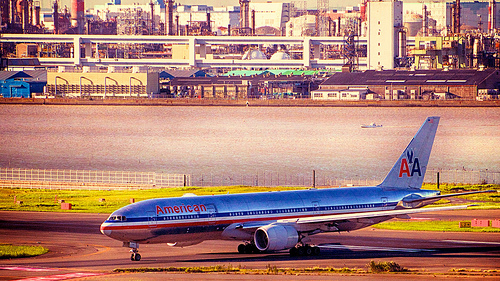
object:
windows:
[162, 216, 167, 221]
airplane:
[98, 115, 500, 261]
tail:
[376, 114, 442, 192]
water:
[0, 108, 499, 180]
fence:
[0, 166, 191, 191]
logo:
[396, 156, 423, 179]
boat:
[358, 118, 384, 130]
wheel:
[129, 248, 143, 262]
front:
[98, 196, 159, 249]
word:
[156, 203, 208, 214]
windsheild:
[105, 214, 126, 225]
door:
[146, 210, 158, 229]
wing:
[274, 204, 468, 225]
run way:
[0, 207, 500, 281]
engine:
[250, 219, 302, 255]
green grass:
[0, 185, 111, 213]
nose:
[98, 203, 134, 245]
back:
[382, 114, 498, 219]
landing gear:
[125, 239, 144, 262]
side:
[104, 195, 408, 234]